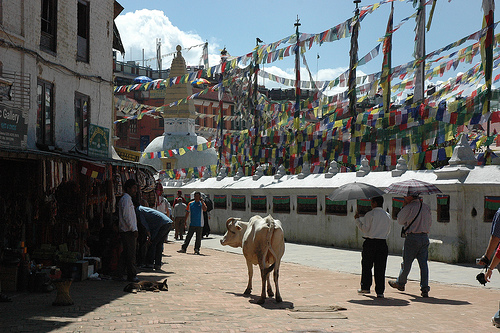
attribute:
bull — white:
[213, 214, 307, 311]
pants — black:
[356, 236, 390, 294]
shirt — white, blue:
[356, 209, 395, 244]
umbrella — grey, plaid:
[326, 178, 387, 202]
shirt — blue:
[186, 202, 207, 229]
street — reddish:
[171, 283, 224, 329]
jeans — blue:
[143, 233, 165, 266]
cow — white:
[240, 217, 285, 295]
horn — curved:
[224, 215, 238, 232]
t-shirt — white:
[122, 202, 137, 223]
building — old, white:
[1, 5, 110, 139]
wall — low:
[86, 70, 107, 88]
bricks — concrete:
[179, 285, 212, 315]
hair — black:
[370, 196, 381, 203]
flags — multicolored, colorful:
[259, 96, 421, 146]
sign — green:
[83, 118, 112, 162]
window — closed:
[77, 13, 90, 57]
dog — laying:
[121, 277, 171, 293]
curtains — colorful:
[215, 70, 310, 134]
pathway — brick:
[293, 245, 335, 267]